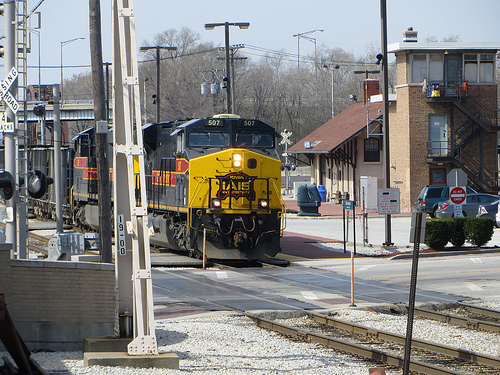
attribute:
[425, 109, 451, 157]
door — metal, grey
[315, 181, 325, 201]
container — blue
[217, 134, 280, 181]
light — yellow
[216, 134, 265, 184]
light — yellow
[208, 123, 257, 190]
light — yellow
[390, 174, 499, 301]
bushes — green